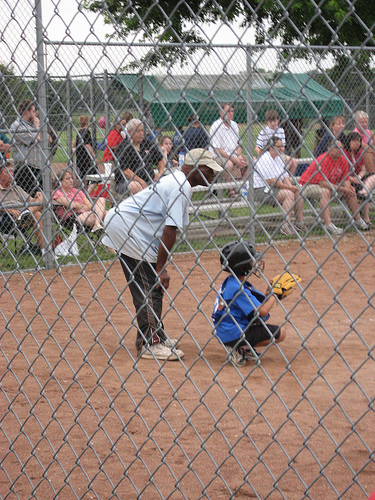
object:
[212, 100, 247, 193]
man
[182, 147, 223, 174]
cap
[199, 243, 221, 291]
ground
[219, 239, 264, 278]
helmet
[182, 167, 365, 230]
bleachers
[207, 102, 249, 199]
spectators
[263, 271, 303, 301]
glove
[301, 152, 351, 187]
shirt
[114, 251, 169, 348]
jogging pants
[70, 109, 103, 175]
people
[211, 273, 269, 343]
shirt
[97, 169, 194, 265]
shirt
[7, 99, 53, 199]
people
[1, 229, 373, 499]
dirt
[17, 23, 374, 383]
fence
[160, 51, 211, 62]
wall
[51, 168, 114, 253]
woman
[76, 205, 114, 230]
legs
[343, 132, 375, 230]
woman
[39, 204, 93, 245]
chair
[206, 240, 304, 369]
catchet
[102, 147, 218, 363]
man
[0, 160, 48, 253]
man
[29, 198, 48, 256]
legs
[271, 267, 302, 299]
hand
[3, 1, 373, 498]
fence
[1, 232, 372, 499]
ground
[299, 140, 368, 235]
man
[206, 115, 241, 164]
shirt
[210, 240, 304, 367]
boy